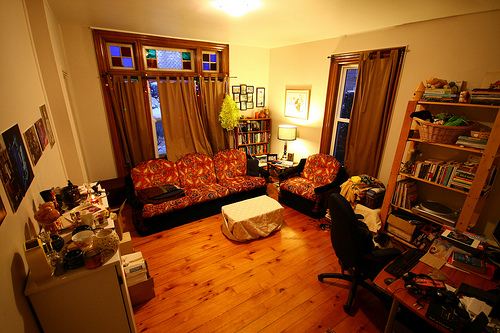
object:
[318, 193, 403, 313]
chair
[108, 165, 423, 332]
floor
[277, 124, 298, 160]
lamp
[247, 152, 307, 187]
table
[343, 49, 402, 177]
curtain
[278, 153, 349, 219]
chair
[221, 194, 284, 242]
table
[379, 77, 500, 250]
shelves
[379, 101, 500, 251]
bookshelf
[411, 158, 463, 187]
books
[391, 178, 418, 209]
books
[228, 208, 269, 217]
cloth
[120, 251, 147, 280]
papers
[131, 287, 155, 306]
box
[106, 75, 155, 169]
curtain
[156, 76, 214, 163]
curtain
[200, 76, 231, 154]
curtain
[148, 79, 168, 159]
window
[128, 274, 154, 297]
box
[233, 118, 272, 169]
bookcase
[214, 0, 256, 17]
light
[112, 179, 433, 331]
wood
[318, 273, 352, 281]
foot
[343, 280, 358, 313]
foot